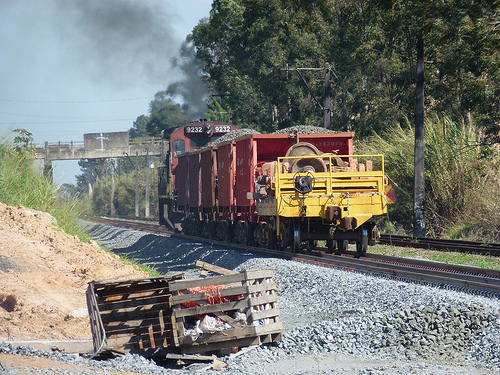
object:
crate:
[167, 270, 284, 361]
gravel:
[484, 347, 498, 366]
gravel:
[324, 129, 329, 132]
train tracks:
[368, 253, 384, 259]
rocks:
[274, 261, 281, 267]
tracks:
[401, 234, 450, 243]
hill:
[0, 184, 104, 271]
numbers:
[187, 127, 203, 133]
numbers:
[226, 126, 230, 132]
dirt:
[6, 307, 15, 332]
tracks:
[399, 258, 425, 265]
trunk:
[415, 115, 429, 239]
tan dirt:
[50, 244, 58, 251]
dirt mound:
[1, 202, 157, 347]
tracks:
[450, 264, 499, 276]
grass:
[0, 186, 15, 206]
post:
[320, 63, 332, 130]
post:
[412, 29, 428, 236]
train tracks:
[144, 218, 158, 223]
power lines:
[1, 99, 55, 104]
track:
[322, 253, 385, 272]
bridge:
[3, 131, 173, 220]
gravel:
[315, 128, 317, 130]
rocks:
[460, 323, 466, 329]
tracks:
[390, 239, 427, 250]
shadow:
[110, 231, 248, 282]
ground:
[298, 333, 500, 373]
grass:
[66, 218, 86, 235]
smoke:
[44, 0, 141, 31]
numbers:
[215, 127, 220, 133]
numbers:
[219, 126, 223, 132]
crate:
[84, 272, 184, 358]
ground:
[1, 354, 147, 373]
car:
[157, 118, 396, 253]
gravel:
[272, 132, 275, 133]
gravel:
[213, 142, 218, 144]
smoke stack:
[199, 117, 208, 121]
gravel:
[300, 126, 304, 130]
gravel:
[216, 138, 220, 141]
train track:
[104, 215, 115, 217]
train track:
[93, 219, 99, 221]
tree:
[375, 0, 494, 234]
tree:
[331, 4, 393, 134]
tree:
[217, 0, 333, 127]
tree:
[187, 0, 243, 103]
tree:
[145, 95, 191, 135]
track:
[220, 242, 230, 246]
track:
[100, 219, 110, 223]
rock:
[356, 308, 365, 315]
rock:
[461, 317, 464, 323]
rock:
[382, 326, 391, 333]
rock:
[326, 333, 333, 340]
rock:
[397, 284, 405, 288]